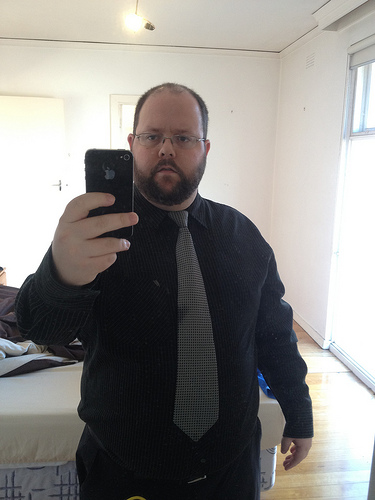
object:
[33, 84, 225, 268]
selfie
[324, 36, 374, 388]
window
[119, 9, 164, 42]
light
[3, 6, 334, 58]
ceiling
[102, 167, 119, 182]
apple logo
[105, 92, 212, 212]
door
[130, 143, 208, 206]
beard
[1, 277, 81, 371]
comforter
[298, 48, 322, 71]
vent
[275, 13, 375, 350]
wall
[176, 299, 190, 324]
stain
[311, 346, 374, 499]
light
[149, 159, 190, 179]
moustache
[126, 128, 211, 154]
glasses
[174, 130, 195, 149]
lense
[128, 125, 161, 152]
lense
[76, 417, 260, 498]
pants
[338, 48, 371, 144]
open window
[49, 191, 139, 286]
hand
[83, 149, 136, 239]
cell phone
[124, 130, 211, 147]
rimless glasses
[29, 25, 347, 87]
wall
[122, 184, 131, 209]
black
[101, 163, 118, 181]
apple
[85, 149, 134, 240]
iphone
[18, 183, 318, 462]
shirt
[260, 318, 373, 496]
floor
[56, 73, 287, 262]
camera phone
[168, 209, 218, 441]
tie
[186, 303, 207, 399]
checkers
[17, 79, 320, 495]
man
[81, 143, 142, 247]
phone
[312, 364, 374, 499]
shining light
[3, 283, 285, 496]
bed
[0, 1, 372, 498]
room